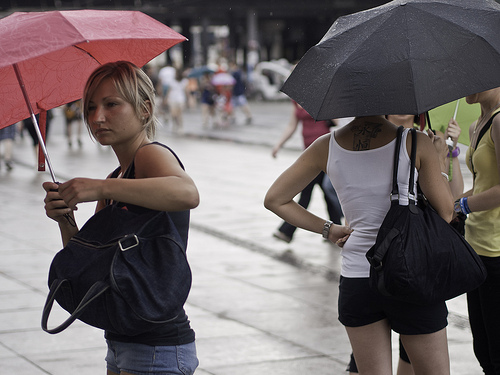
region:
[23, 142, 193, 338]
a large blue bag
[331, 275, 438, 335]
a woman's black shorts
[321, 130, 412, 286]
a woman's white tank top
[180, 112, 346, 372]
part of a concrete sidewalk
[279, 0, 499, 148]
a black umbrella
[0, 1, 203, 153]
part of a red umbrella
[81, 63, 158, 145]
a woman's blonde hair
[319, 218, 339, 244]
a woman's watch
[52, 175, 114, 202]
the hand of a woman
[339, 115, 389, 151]
a woman's back tattoo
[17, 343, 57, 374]
Small line in the pavement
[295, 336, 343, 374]
Small line in the pavement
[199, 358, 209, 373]
Small line in the pavement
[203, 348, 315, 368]
Small line in the pavement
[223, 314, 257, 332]
Small line in the pavement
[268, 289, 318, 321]
Small line in the pavement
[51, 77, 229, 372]
PErson standing on the pavement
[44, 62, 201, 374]
woman under red umbrella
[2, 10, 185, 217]
red umbrella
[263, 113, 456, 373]
woman holding black umbrella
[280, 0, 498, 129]
black umbrella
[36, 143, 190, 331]
denim bag held by woman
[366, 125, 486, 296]
large black bag on shoulder of woman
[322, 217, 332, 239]
silver watch on wrist of woman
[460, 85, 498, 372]
woman wearing yellow tank top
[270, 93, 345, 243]
person wearing dark pink shirt behind group of women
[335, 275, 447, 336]
black shorts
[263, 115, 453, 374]
A young woman with black umbrella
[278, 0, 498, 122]
A black wet umbrella held by a woman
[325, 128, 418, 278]
White tank top the woman is wearing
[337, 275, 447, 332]
Black shorts the woman is wearing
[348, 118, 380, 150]
A tattoo on the woman's neck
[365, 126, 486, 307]
A black big purse the woman is carrying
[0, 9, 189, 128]
Pink umbrella of a blond woman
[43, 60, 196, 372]
A woman with blond hair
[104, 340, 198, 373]
Blue denim shorts the woman is wearing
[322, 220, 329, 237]
Wristwatch strap around the woman's wrist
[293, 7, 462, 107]
open black umbrella in hand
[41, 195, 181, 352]
black bag on woman's side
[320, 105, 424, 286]
white tank top on woman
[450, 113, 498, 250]
yellow tank top on woman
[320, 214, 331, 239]
wrist watch on arm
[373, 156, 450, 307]
black bag on woman's side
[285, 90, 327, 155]
pink shirt on woman